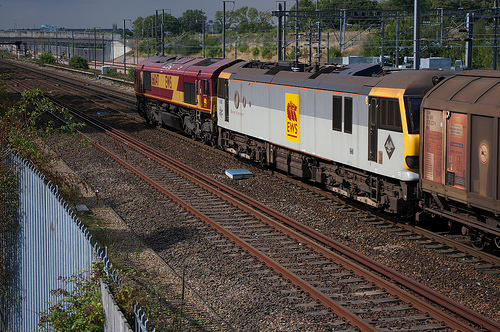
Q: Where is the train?
A: On tracks.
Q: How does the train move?
A: On wheels and tracks.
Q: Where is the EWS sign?
A: On the side of the train.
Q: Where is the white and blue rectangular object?
A: Next to the train.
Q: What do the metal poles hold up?
A: Wires.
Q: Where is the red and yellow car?
A: Behind the train engine.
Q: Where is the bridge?
A: In the near distance.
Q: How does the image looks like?
A: Good.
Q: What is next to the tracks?
A: Cliff.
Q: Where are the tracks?
A: On ground.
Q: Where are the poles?
A: Next to train.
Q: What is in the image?
A: Rusted set of trains.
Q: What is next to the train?
A: Blue iron fence.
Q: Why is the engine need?
A: To run.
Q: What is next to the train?
A: Trees.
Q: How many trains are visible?
A: One.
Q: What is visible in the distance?
A: An overpass.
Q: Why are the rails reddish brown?
A: They're rustyl.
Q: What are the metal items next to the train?
A: More train tracks.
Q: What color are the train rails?
A: Brown.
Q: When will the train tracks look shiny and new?
A: Never again.